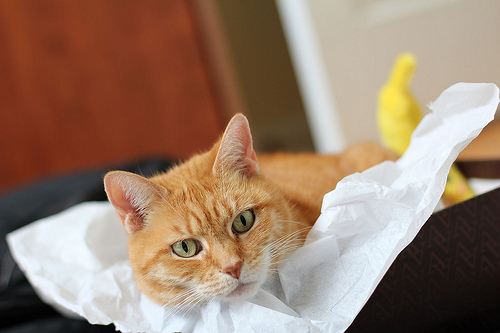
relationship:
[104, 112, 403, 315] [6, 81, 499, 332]
cat on bag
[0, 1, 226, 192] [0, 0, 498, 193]
door in background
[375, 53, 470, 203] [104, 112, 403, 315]
toy behind cat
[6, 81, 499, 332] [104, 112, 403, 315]
bag layed on by cat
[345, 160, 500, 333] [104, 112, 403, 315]
furniture under cat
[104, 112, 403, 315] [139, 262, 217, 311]
cat has whisker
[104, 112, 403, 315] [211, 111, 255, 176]
cat has ear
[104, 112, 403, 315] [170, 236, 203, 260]
cat has eye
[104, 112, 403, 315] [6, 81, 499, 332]
cat sitting on bag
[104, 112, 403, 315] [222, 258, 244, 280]
cat has nose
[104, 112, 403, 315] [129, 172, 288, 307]
cat has face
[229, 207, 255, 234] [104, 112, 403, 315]
eye of cat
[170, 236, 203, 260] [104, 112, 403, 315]
eye of cat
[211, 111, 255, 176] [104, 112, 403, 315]
ear of cat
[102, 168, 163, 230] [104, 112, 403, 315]
ear of cat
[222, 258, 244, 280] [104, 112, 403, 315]
nose of cat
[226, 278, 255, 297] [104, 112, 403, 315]
mouth of cat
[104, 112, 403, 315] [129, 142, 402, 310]
cat with fur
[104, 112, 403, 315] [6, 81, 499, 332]
cat lying on bag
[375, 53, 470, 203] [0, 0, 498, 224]
banana in distance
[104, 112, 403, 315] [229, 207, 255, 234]
cat has eye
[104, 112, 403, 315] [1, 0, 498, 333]
cat in picture